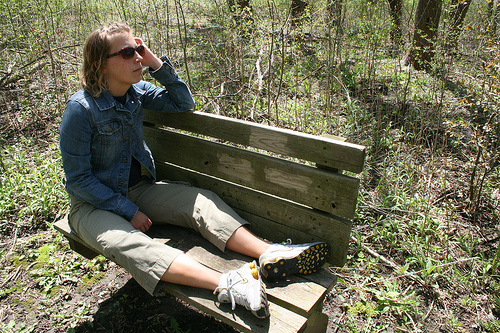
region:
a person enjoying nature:
[42, 16, 320, 313]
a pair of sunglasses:
[100, 39, 150, 62]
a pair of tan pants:
[67, 180, 239, 285]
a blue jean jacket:
[50, 74, 205, 214]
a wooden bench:
[35, 90, 398, 328]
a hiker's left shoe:
[255, 234, 348, 294]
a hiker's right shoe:
[214, 261, 274, 321]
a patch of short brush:
[5, 8, 498, 317]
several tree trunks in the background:
[221, 0, 498, 75]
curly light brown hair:
[68, 33, 110, 103]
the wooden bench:
[52, 106, 364, 331]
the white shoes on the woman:
[211, 237, 328, 319]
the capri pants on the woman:
[67, 178, 253, 297]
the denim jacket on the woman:
[60, 55, 196, 220]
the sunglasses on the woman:
[104, 43, 145, 60]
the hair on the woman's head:
[81, 21, 130, 96]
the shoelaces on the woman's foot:
[212, 278, 247, 310]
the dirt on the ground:
[0, 1, 497, 331]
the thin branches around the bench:
[0, 0, 498, 331]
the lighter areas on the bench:
[215, 126, 310, 192]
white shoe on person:
[206, 260, 294, 316]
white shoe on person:
[258, 233, 331, 279]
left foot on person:
[251, 232, 333, 284]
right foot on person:
[219, 259, 274, 319]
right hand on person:
[120, 195, 163, 239]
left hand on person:
[134, 29, 176, 69]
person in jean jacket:
[51, 17, 256, 232]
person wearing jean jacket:
[46, 9, 253, 263]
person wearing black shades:
[74, 24, 171, 108]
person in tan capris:
[76, 23, 287, 306]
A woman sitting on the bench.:
[66, 32, 282, 289]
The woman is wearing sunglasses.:
[99, 37, 149, 59]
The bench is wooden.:
[192, 114, 360, 331]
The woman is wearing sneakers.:
[209, 244, 314, 310]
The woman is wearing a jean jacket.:
[56, 104, 146, 158]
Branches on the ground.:
[371, 234, 461, 310]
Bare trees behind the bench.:
[256, 11, 412, 105]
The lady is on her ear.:
[133, 30, 176, 85]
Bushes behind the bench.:
[228, 19, 465, 154]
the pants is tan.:
[93, 198, 293, 253]